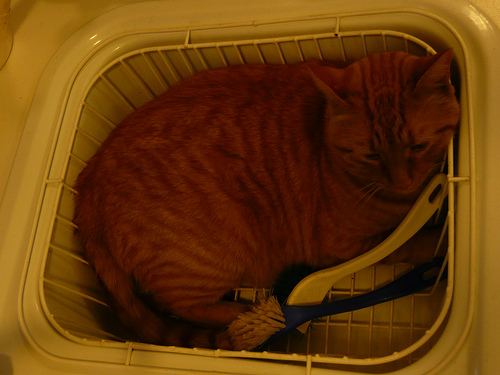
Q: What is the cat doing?
A: Laying down.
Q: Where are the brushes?
A: In sink.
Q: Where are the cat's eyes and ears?
A: Cat's head.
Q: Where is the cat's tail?
A: Sink.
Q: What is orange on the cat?
A: Fur.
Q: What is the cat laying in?
A: Sink.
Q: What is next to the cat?
A: Brushes.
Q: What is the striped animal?
A: Cat.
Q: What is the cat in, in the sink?
A: Basket.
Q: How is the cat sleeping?
A: Lying.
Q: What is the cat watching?
A: Nothing.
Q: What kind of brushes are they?
A: Scrubbing.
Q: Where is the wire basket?
A: Sink.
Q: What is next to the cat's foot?
A: Brushes.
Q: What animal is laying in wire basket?
A: Cat.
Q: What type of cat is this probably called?
A: Orange tabby.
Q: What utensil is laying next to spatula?
A: Dish washing brush.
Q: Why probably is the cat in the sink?
A: It is a cool place.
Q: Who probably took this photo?
A: Cat's owner.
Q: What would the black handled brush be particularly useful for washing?
A: Drinking glasses.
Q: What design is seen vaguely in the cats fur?
A: Stripes.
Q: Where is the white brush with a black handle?
A: Next to the cat.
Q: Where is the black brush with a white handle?
A: Next to the cat.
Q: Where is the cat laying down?
A: Metal basket in a sink.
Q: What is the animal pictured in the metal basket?
A: A cat.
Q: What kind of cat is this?
A: An orange cat with stripes.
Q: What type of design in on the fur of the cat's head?
A: Vertical stripes.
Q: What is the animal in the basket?
A: An orange cat with stripes.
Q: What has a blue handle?
A: A dish brush.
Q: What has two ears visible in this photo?
A: The cat.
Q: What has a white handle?
A: The brush.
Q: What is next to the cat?
A: Brushes.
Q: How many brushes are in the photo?
A: Two.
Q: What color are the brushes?
A: Blue and white.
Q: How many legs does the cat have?
A: Four.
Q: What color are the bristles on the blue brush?
A: White.